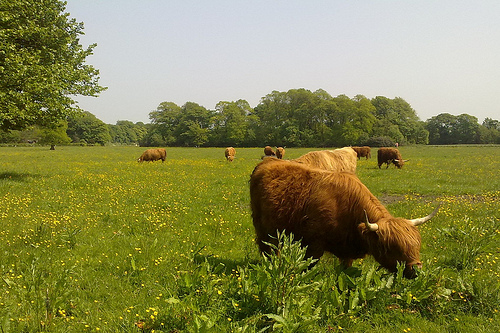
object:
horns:
[409, 202, 443, 226]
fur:
[248, 159, 421, 264]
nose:
[402, 262, 424, 279]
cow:
[377, 148, 411, 170]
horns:
[394, 158, 400, 161]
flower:
[55, 304, 67, 313]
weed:
[126, 259, 146, 282]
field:
[0, 144, 499, 332]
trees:
[482, 119, 500, 147]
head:
[356, 205, 439, 280]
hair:
[375, 220, 421, 253]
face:
[375, 221, 428, 280]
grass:
[0, 143, 500, 332]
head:
[275, 146, 287, 155]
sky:
[43, 1, 499, 127]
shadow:
[179, 253, 292, 318]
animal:
[248, 157, 438, 279]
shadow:
[0, 169, 34, 184]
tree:
[1, 0, 108, 133]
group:
[138, 146, 439, 282]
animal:
[289, 147, 358, 177]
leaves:
[1, 0, 45, 36]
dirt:
[378, 184, 439, 204]